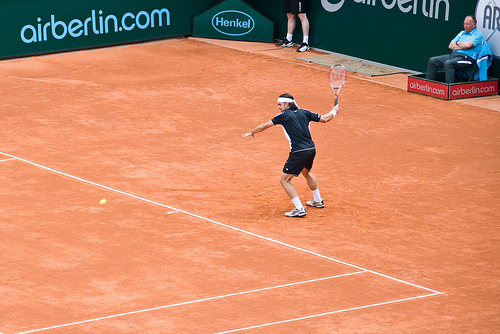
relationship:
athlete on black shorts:
[240, 92, 340, 217] [282, 148, 317, 177]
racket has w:
[321, 60, 348, 126] [330, 67, 345, 85]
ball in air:
[91, 188, 106, 215] [2, 3, 497, 331]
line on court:
[16, 263, 370, 331] [0, 34, 498, 330]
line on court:
[5, 270, 443, 334] [0, 34, 498, 330]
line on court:
[6, 153, 441, 298] [0, 34, 498, 330]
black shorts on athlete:
[282, 148, 317, 177] [240, 92, 344, 218]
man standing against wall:
[275, 0, 311, 53] [324, 1, 424, 49]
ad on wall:
[18, 7, 173, 44] [0, 0, 500, 71]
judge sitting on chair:
[426, 15, 483, 84] [461, 65, 475, 82]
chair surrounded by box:
[461, 65, 475, 82] [405, 71, 499, 100]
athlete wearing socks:
[240, 92, 340, 217] [288, 195, 305, 212]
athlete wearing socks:
[240, 92, 340, 217] [309, 185, 323, 203]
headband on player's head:
[277, 97, 300, 109] [271, 87, 305, 116]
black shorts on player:
[274, 142, 319, 180] [244, 90, 342, 220]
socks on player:
[251, 195, 344, 232] [244, 90, 342, 220]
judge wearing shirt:
[426, 15, 483, 84] [449, 29, 490, 61]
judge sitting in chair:
[422, 10, 484, 85] [444, 53, 481, 86]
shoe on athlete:
[302, 195, 323, 210] [240, 92, 340, 217]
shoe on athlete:
[280, 207, 305, 217] [240, 92, 340, 217]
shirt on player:
[269, 109, 321, 152] [244, 90, 342, 220]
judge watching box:
[426, 15, 483, 84] [405, 71, 499, 101]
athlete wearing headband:
[240, 92, 340, 217] [275, 95, 295, 102]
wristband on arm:
[329, 109, 339, 117] [299, 103, 340, 122]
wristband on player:
[329, 109, 339, 117] [244, 90, 342, 220]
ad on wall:
[0, 0, 183, 45] [0, 6, 492, 85]